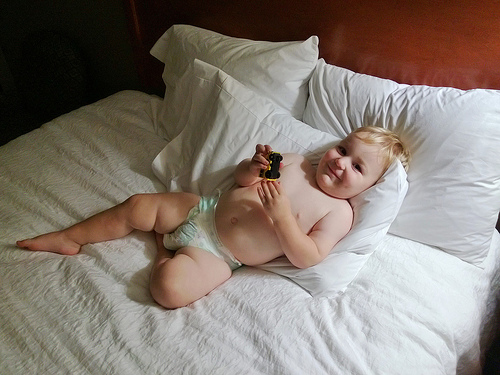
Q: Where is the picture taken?
A: A bedroom.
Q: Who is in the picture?
A: A child.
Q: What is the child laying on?
A: A bed.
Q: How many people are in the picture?
A: One.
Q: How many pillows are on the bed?
A: Three.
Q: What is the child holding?
A: A toy car.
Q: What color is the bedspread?
A: White.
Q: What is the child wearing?
A: A diaper.